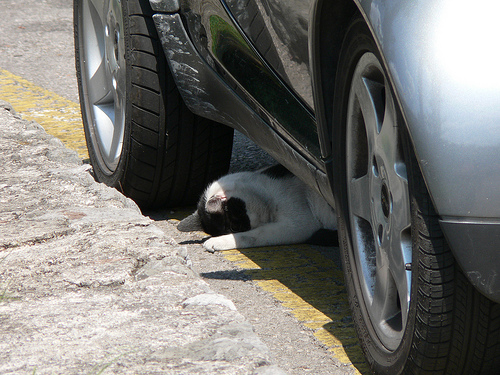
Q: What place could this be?
A: It is a road.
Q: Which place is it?
A: It is a road.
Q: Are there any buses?
A: No, there are no buses.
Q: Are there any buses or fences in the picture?
A: No, there are no buses or fences.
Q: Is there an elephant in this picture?
A: No, there are no elephants.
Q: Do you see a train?
A: No, there are no trains.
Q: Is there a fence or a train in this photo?
A: No, there are no trains or fences.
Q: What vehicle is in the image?
A: The vehicle is a car.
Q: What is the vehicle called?
A: The vehicle is a car.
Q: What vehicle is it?
A: The vehicle is a car.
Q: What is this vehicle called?
A: That is a car.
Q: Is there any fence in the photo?
A: No, there are no fences.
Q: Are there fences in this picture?
A: No, there are no fences.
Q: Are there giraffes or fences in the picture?
A: No, there are no fences or giraffes.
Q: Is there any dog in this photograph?
A: No, there are no dogs.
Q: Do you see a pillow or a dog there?
A: No, there are no dogs or pillows.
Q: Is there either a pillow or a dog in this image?
A: No, there are no dogs or pillows.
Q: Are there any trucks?
A: No, there are no trucks.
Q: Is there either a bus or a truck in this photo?
A: No, there are no trucks or buses.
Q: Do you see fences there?
A: No, there are no fences.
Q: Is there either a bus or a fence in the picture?
A: No, there are no fences or buses.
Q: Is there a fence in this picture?
A: No, there are no fences.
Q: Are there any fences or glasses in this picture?
A: No, there are no fences or glasses.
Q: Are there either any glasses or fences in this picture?
A: No, there are no fences or glasses.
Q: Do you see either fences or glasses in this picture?
A: No, there are no fences or glasses.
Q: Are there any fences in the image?
A: No, there are no fences.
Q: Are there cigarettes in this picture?
A: No, there are no cigarettes.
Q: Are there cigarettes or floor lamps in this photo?
A: No, there are no cigarettes or floor lamps.